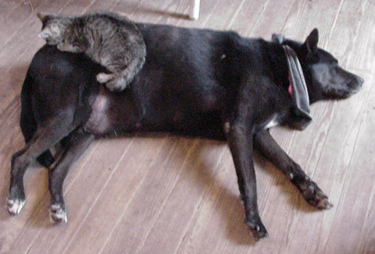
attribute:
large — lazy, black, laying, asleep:
[18, 18, 362, 201]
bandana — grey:
[268, 30, 321, 132]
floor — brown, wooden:
[4, 9, 23, 102]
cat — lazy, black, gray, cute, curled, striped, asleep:
[30, 7, 149, 98]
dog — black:
[15, 8, 363, 185]